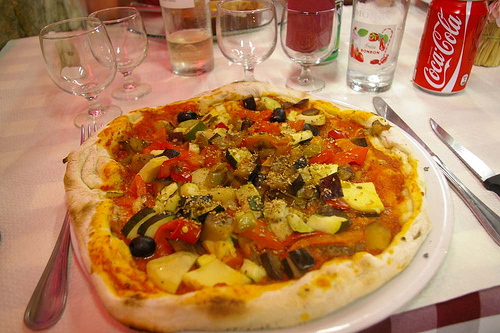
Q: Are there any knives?
A: Yes, there is a knife.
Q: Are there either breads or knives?
A: Yes, there is a knife.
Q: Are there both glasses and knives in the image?
A: Yes, there are both a knife and glasses.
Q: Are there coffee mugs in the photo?
A: No, there are no coffee mugs.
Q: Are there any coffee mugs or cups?
A: No, there are no coffee mugs or cups.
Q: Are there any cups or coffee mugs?
A: No, there are no coffee mugs or cups.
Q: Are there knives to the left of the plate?
A: No, the knife is to the right of the plate.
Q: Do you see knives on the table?
A: Yes, there is a knife on the table.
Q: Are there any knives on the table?
A: Yes, there is a knife on the table.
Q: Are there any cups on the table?
A: No, there is a knife on the table.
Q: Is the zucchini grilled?
A: Yes, the zucchini is grilled.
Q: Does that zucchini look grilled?
A: Yes, the zucchini is grilled.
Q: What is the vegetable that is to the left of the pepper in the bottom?
A: The vegetable is a zucchini.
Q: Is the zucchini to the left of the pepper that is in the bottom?
A: Yes, the zucchini is to the left of the pepper.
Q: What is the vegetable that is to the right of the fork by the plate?
A: The vegetable is a zucchini.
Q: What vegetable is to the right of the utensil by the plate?
A: The vegetable is a zucchini.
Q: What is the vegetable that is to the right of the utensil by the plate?
A: The vegetable is a zucchini.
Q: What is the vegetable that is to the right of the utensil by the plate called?
A: The vegetable is a zucchini.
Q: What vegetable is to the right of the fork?
A: The vegetable is a zucchini.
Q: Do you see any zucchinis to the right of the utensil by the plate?
A: Yes, there is a zucchini to the right of the fork.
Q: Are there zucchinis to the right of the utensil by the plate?
A: Yes, there is a zucchini to the right of the fork.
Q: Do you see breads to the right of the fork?
A: No, there is a zucchini to the right of the fork.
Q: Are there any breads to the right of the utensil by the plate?
A: No, there is a zucchini to the right of the fork.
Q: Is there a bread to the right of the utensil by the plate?
A: No, there is a zucchini to the right of the fork.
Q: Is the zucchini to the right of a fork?
A: Yes, the zucchini is to the right of a fork.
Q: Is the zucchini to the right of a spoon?
A: No, the zucchini is to the right of a fork.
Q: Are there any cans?
A: Yes, there is a can.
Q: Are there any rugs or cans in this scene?
A: Yes, there is a can.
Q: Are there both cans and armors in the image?
A: No, there is a can but no armors.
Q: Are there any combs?
A: No, there are no combs.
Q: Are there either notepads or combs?
A: No, there are no combs or notepads.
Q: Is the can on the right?
A: Yes, the can is on the right of the image.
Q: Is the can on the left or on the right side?
A: The can is on the right of the image.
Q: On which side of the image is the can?
A: The can is on the right of the image.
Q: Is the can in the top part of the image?
A: Yes, the can is in the top of the image.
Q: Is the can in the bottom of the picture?
A: No, the can is in the top of the image.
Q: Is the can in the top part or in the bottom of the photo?
A: The can is in the top of the image.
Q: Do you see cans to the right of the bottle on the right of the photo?
A: Yes, there is a can to the right of the bottle.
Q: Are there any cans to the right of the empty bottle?
A: Yes, there is a can to the right of the bottle.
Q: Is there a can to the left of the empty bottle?
A: No, the can is to the right of the bottle.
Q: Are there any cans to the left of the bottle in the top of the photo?
A: No, the can is to the right of the bottle.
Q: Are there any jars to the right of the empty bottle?
A: No, there is a can to the right of the bottle.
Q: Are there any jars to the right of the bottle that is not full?
A: No, there is a can to the right of the bottle.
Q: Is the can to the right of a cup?
A: No, the can is to the right of the bottle.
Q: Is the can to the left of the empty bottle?
A: No, the can is to the right of the bottle.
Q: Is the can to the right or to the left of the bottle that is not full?
A: The can is to the right of the bottle.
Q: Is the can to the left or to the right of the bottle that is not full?
A: The can is to the right of the bottle.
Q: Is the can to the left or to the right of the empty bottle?
A: The can is to the right of the bottle.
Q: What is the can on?
A: The can is on the table.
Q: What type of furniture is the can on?
A: The can is on the table.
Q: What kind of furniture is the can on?
A: The can is on the table.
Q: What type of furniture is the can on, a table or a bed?
A: The can is on a table.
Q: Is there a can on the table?
A: Yes, there is a can on the table.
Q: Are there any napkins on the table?
A: No, there is a can on the table.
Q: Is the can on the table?
A: Yes, the can is on the table.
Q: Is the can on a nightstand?
A: No, the can is on the table.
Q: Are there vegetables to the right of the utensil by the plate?
A: Yes, there is a vegetable to the right of the fork.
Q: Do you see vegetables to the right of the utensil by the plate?
A: Yes, there is a vegetable to the right of the fork.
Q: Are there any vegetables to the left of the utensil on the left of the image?
A: No, the vegetable is to the right of the fork.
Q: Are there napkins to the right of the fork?
A: No, there is a vegetable to the right of the fork.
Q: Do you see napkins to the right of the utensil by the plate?
A: No, there is a vegetable to the right of the fork.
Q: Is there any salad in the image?
A: No, there is no salad.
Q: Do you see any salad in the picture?
A: No, there is no salad.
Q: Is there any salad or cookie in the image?
A: No, there are no salad or cookies.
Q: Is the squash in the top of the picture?
A: No, the squash is in the bottom of the image.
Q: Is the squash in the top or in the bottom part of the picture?
A: The squash is in the bottom of the image.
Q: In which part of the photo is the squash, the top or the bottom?
A: The squash is in the bottom of the image.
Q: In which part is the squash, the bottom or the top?
A: The squash is in the bottom of the image.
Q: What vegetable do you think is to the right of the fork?
A: The vegetable is a squash.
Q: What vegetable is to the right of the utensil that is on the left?
A: The vegetable is a squash.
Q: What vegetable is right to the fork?
A: The vegetable is a squash.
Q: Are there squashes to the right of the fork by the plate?
A: Yes, there is a squash to the right of the fork.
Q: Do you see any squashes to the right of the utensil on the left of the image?
A: Yes, there is a squash to the right of the fork.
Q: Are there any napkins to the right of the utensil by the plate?
A: No, there is a squash to the right of the fork.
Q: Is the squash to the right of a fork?
A: Yes, the squash is to the right of a fork.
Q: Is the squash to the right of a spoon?
A: No, the squash is to the right of a fork.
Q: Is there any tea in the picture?
A: Yes, there is tea.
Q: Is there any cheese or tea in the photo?
A: Yes, there is tea.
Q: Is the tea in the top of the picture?
A: Yes, the tea is in the top of the image.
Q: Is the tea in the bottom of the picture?
A: No, the tea is in the top of the image.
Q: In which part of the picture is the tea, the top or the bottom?
A: The tea is in the top of the image.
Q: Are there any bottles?
A: Yes, there is a bottle.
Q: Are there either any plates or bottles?
A: Yes, there is a bottle.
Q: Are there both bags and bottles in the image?
A: No, there is a bottle but no bags.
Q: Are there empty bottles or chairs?
A: Yes, there is an empty bottle.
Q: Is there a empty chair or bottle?
A: Yes, there is an empty bottle.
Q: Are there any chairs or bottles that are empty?
A: Yes, the bottle is empty.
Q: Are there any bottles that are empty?
A: Yes, there is an empty bottle.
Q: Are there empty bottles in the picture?
A: Yes, there is an empty bottle.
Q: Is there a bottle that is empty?
A: Yes, there is a bottle that is empty.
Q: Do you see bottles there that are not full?
A: Yes, there is a empty bottle.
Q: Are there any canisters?
A: No, there are no canisters.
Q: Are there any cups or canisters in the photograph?
A: No, there are no canisters or cups.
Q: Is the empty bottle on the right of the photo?
A: Yes, the bottle is on the right of the image.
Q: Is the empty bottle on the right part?
A: Yes, the bottle is on the right of the image.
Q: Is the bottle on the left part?
A: No, the bottle is on the right of the image.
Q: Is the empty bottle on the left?
A: No, the bottle is on the right of the image.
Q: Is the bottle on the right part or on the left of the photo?
A: The bottle is on the right of the image.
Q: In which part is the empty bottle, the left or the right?
A: The bottle is on the right of the image.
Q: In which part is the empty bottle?
A: The bottle is on the right of the image.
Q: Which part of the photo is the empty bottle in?
A: The bottle is on the right of the image.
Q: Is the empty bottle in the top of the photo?
A: Yes, the bottle is in the top of the image.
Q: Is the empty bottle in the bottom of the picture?
A: No, the bottle is in the top of the image.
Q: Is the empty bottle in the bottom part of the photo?
A: No, the bottle is in the top of the image.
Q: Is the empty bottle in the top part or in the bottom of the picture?
A: The bottle is in the top of the image.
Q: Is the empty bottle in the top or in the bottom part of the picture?
A: The bottle is in the top of the image.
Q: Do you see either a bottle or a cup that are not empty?
A: No, there is a bottle but it is empty.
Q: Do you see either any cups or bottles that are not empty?
A: No, there is a bottle but it is empty.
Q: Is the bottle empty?
A: Yes, the bottle is empty.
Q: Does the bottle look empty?
A: Yes, the bottle is empty.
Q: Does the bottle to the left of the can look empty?
A: Yes, the bottle is empty.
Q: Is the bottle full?
A: No, the bottle is empty.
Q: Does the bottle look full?
A: No, the bottle is empty.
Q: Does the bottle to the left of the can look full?
A: No, the bottle is empty.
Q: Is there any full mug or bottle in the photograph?
A: No, there is a bottle but it is empty.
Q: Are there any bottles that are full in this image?
A: No, there is a bottle but it is empty.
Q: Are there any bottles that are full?
A: No, there is a bottle but it is empty.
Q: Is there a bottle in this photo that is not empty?
A: No, there is a bottle but it is empty.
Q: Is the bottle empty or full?
A: The bottle is empty.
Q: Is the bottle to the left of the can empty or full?
A: The bottle is empty.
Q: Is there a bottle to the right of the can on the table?
A: No, the bottle is to the left of the can.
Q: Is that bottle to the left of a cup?
A: No, the bottle is to the left of the can.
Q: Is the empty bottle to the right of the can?
A: No, the bottle is to the left of the can.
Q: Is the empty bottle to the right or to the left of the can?
A: The bottle is to the left of the can.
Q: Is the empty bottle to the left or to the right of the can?
A: The bottle is to the left of the can.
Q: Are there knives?
A: Yes, there is a knife.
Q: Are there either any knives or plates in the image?
A: Yes, there is a knife.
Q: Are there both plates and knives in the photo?
A: Yes, there are both a knife and a plate.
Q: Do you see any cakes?
A: No, there are no cakes.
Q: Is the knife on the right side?
A: Yes, the knife is on the right of the image.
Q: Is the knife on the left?
A: No, the knife is on the right of the image.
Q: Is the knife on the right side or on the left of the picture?
A: The knife is on the right of the image.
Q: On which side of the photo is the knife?
A: The knife is on the right of the image.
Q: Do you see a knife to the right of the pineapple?
A: Yes, there is a knife to the right of the pineapple.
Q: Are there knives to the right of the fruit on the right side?
A: Yes, there is a knife to the right of the pineapple.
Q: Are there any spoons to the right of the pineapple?
A: No, there is a knife to the right of the pineapple.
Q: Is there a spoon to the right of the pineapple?
A: No, there is a knife to the right of the pineapple.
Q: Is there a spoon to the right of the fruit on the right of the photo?
A: No, there is a knife to the right of the pineapple.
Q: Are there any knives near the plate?
A: Yes, there is a knife near the plate.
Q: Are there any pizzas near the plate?
A: No, there is a knife near the plate.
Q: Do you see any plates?
A: Yes, there is a plate.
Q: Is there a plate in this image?
A: Yes, there is a plate.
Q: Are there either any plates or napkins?
A: Yes, there is a plate.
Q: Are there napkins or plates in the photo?
A: Yes, there is a plate.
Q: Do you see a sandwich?
A: No, there are no sandwiches.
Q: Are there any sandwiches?
A: No, there are no sandwiches.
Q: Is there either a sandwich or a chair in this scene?
A: No, there are no sandwiches or chairs.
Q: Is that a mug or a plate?
A: That is a plate.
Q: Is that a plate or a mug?
A: That is a plate.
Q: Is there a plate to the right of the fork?
A: Yes, there is a plate to the right of the fork.